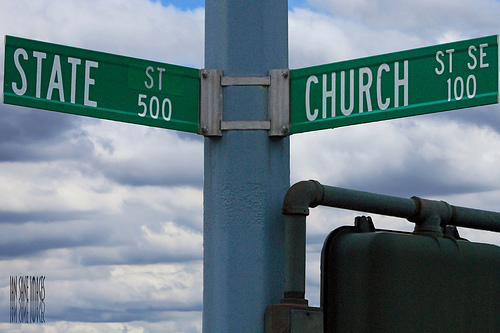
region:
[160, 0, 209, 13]
blue of daytime sky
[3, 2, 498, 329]
cloud cover in sky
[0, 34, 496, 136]
two green streets signs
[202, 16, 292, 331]
blue pole with metal brace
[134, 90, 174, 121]
white number on green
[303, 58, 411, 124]
white word on green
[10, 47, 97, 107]
five letters of word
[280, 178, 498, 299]
two poles attached with elbow pipe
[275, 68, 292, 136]
two bolts on metal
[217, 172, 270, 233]
rough surface of pole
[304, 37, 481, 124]
green and white street sign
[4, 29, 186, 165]
green and white sign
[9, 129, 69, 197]
white clouds in blue sky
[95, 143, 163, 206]
white clouds in blue sky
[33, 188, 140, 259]
white clouds in blue sky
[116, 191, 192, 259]
white clouds in blue sky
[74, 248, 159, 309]
white clouds in blue sky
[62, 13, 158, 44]
white clouds in blue sky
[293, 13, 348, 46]
white clouds in blue sky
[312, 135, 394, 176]
white clouds in blue sky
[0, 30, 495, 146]
green signs on gray pole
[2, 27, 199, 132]
white print of letters and numbers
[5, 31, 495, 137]
street signs flaring outwards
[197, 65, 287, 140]
metal band and screws holding signs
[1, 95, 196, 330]
rows of gray and white clouds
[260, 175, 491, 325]
curved metal piping in base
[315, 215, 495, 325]
curved hanging panel from rod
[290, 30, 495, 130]
raised border on edges of sign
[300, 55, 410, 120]
word with two repeated letters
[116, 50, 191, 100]
lighter green panel on sign with two letters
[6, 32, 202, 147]
street sign with green background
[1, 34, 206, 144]
street sign with white letters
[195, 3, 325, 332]
blue utility post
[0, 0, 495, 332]
cloudy sky with small opening of blue sky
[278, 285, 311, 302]
threads on end of pipe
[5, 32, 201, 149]
sign with green background and white letters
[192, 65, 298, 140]
grey colored sign brackets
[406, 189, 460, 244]
pipe fitting in the shape of a t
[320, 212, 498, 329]
green metal box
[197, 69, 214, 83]
small bolt on sign bracket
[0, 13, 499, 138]
a sign showing cross streets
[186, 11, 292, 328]
this is a pole with street signs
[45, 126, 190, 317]
there are white heavy clouds in the sky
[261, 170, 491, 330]
this is the back of what is most likely a traffic light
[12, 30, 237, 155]
the sign is green with white lettering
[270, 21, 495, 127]
the sign contains the address of the area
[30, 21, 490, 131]
there are two street signs on the pole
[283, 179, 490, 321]
the back of the traffic light is black in color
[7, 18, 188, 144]
this sign is for State St.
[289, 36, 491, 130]
this sign is for Church Street